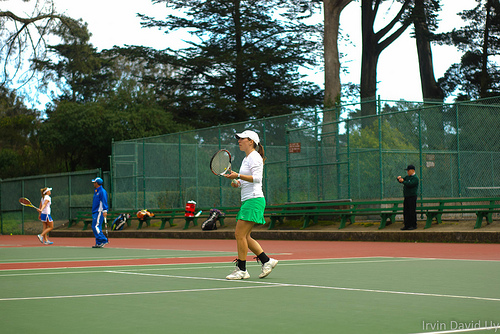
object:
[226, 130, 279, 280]
woman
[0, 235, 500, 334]
tennis court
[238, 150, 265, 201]
jersey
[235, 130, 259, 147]
cone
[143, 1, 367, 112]
trees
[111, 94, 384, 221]
fence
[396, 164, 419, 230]
man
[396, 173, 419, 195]
sweatshirt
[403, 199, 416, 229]
pants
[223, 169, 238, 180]
hand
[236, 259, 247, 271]
sock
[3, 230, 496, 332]
photo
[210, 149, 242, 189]
racket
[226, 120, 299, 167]
wall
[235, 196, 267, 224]
skirt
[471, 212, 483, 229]
legs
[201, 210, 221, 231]
bag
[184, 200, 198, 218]
bag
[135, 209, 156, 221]
bag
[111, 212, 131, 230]
bag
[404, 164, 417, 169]
hat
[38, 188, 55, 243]
woman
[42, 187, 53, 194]
visor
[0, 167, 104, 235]
fence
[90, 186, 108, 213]
blue clothes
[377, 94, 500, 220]
fence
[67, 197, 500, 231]
bench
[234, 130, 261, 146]
cap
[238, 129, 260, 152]
head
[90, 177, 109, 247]
man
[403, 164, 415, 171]
hat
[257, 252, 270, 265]
sock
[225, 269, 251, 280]
shoe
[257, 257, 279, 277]
shoe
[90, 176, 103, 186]
hat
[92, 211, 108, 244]
clothes